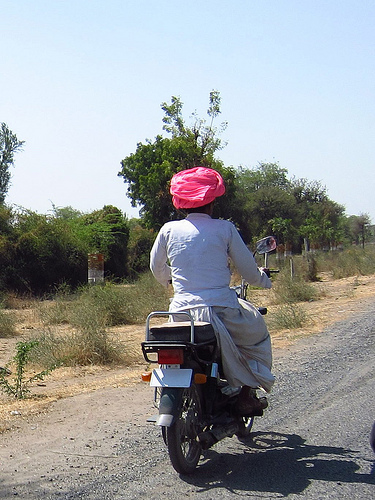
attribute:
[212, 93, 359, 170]
clouds — white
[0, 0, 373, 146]
sky — blue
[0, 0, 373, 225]
clouds — White 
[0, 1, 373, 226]
sky — blue 